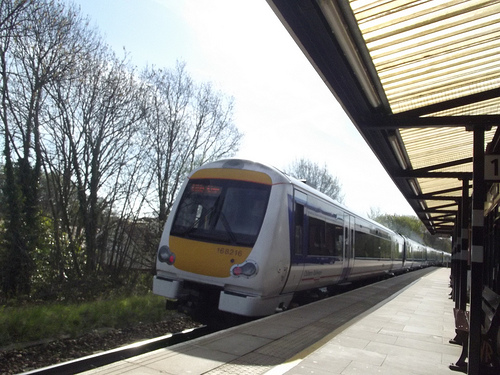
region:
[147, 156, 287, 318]
Yellow and white front of train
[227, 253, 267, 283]
yellow and white train headlights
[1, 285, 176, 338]
green grass next to train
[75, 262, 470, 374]
standing platform next to train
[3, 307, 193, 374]
gravel by the train tracks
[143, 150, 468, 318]
train next to station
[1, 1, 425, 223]
blue sky with white clouds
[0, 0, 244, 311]
brown and barren trees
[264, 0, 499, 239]
roof of building at station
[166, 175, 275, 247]
window at head of train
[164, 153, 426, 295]
yellow and white train at train depot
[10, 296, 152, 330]
green grass next to train tracks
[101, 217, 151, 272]
brown roof of white house in the woods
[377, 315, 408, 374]
brick tiles on the train platform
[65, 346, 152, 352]
metal track train on the ground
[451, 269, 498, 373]
brown empty bench attached to the floor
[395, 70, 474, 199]
plastic roof of train depot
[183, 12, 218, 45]
white cloud in blue sky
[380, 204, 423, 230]
green tree behind train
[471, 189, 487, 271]
white marking on metal post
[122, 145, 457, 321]
the train is yellow and white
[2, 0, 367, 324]
the trees beside the train are bare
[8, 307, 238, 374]
the train track is shiny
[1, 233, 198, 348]
the train has green grass beside it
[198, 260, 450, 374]
the walkway beside the train is white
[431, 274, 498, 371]
a brown bench sits on the walkway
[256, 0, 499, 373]
the brown bench is under a canopy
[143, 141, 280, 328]
the front of the train has lights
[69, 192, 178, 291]
part of a house can be seen through the trees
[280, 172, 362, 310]
the train has doors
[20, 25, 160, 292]
tall straight trees with no leaves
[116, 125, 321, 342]
train entering an outdoor station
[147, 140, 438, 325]
modern and streamlined train in yellow and white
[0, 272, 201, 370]
row of green plants growing parallel to tracks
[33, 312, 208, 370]
silver train rail shining brightly in sun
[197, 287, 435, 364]
grey tiles covering the train platform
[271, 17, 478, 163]
tan ridged roof covering with dark edge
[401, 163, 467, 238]
roofing supports in zigzag pattern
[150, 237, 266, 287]
silver and orange headlights on front of train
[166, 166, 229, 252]
train window with route information on top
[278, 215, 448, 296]
train with passenger cars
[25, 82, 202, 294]
trees bare of leaves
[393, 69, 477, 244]
station roof's overhang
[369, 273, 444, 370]
tiled surface on the platform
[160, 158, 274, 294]
yellow front of the train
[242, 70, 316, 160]
gray overcast sky overhead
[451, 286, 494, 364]
empty brown wooden bench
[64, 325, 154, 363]
dead leaves beside the train tracks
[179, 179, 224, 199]
electric display on front of train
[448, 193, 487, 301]
metal poles supporting roof overhang